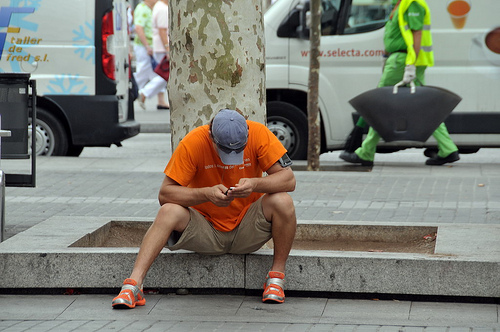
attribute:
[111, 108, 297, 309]
man — sitting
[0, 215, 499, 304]
curb — grey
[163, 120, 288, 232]
shirt — orange, orange in color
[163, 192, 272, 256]
shorts — khaki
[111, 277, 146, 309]
shoe — orange, grey, silver, orange in color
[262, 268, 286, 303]
shoe — orange, grey, silver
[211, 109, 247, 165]
cap — blue, grey nike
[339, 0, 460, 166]
man — walking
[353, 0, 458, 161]
clothing — green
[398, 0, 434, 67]
vest — reflector, safety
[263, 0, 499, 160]
van — white, parked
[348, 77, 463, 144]
bag — black